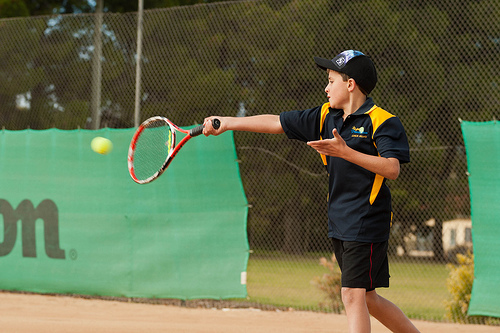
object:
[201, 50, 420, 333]
boy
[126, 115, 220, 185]
tennis racket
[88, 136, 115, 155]
ball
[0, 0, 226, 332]
air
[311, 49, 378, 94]
hat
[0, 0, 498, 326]
fence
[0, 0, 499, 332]
court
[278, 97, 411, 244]
shirt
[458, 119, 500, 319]
material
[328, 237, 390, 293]
shorts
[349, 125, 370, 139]
sign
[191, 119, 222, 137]
handle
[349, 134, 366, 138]
word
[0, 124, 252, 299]
tarp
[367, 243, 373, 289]
line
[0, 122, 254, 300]
banner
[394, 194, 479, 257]
building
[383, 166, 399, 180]
elbow